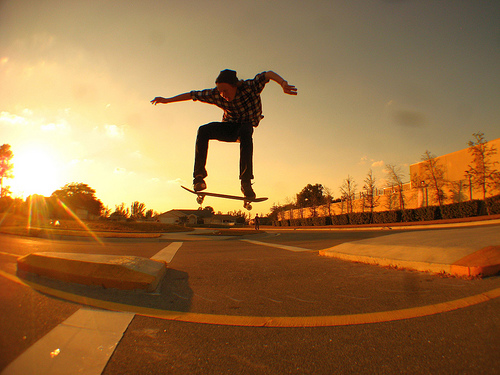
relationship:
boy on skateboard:
[152, 62, 297, 192] [178, 181, 270, 214]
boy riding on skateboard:
[150, 69, 297, 199] [182, 183, 268, 211]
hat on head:
[212, 67, 242, 90] [212, 63, 242, 105]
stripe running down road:
[105, 283, 495, 350] [127, 240, 377, 371]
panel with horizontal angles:
[318, 219, 499, 285] [12, 255, 167, 297]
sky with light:
[0, 4, 460, 149] [2, 146, 89, 218]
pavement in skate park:
[0, 232, 500, 373] [0, 214, 499, 373]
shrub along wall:
[460, 131, 499, 213] [275, 172, 498, 220]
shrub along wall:
[411, 146, 454, 217] [275, 172, 498, 220]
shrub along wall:
[375, 157, 412, 217] [275, 172, 498, 220]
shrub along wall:
[358, 159, 383, 224] [275, 172, 498, 220]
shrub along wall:
[318, 185, 338, 230] [275, 172, 498, 220]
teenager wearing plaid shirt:
[150, 69, 298, 199] [203, 75, 274, 132]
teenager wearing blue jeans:
[153, 68, 300, 199] [189, 120, 254, 187]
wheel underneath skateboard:
[195, 197, 202, 203] [179, 184, 269, 210]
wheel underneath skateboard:
[242, 202, 247, 207] [179, 184, 269, 210]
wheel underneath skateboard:
[245, 203, 252, 210] [179, 184, 269, 210]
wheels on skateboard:
[193, 192, 203, 203] [179, 180, 268, 210]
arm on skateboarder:
[254, 59, 303, 96] [180, 56, 288, 206]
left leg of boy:
[236, 122, 258, 194] [150, 69, 297, 199]